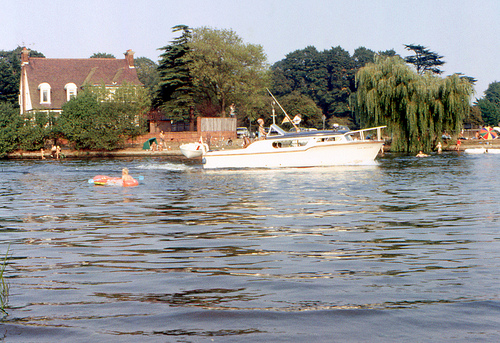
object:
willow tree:
[358, 53, 471, 158]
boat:
[195, 116, 389, 176]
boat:
[202, 122, 386, 167]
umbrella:
[479, 119, 496, 151]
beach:
[7, 111, 487, 165]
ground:
[426, 145, 436, 150]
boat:
[203, 117, 385, 172]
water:
[0, 147, 498, 342]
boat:
[200, 119, 392, 179]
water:
[56, 168, 461, 286]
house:
[10, 37, 155, 134]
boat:
[200, 87, 386, 177]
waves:
[1, 177, 498, 338]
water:
[252, 187, 444, 297]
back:
[249, 190, 446, 312]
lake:
[31, 194, 431, 291]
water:
[288, 200, 463, 311]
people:
[27, 131, 70, 161]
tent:
[138, 131, 160, 154]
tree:
[356, 56, 475, 163]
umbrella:
[476, 122, 498, 145]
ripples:
[135, 320, 269, 340]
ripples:
[174, 222, 306, 244]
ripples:
[204, 192, 271, 211]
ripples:
[80, 221, 157, 248]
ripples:
[391, 232, 482, 256]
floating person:
[81, 163, 149, 197]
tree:
[138, 17, 265, 157]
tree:
[277, 42, 365, 131]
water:
[224, 185, 367, 265]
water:
[69, 187, 296, 263]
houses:
[16, 31, 221, 131]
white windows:
[30, 75, 80, 111]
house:
[15, 47, 147, 129]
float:
[78, 173, 139, 194]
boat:
[191, 89, 401, 183]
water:
[186, 198, 434, 284]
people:
[52, 163, 256, 192]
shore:
[460, 124, 490, 154]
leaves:
[310, 64, 334, 97]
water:
[41, 193, 460, 230]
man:
[120, 168, 132, 179]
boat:
[196, 88, 387, 167]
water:
[37, 202, 458, 327]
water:
[48, 204, 451, 339]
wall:
[11, 129, 181, 157]